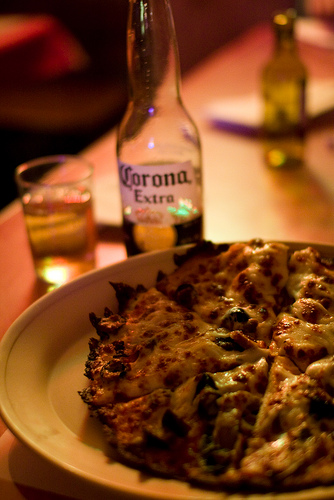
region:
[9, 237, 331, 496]
a white plate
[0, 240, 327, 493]
the plate has food on it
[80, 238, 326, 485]
pizza is on the plate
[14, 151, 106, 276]
a glass cup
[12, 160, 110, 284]
a drink is in the glass cup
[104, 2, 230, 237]
a glass bottle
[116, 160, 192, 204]
words on the glass bottle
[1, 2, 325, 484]
a counter with drinks and a plate on it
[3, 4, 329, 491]
The counter is a light brown color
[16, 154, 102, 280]
the drink is a tan color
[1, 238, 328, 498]
Pizza sitting on plate on table.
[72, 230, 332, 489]
Slices of pizza on plate.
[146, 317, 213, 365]
Melted cheese on pizza.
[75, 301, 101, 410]
Brown crust edge on pizza.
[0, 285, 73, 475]
Edge of plate pizza sitting on.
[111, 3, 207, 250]
Bottle of Corona beer sitting on table.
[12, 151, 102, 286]
Glass of Corona beer sitting on table.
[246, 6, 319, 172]
Empty beer bottle sitting on table.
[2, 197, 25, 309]
Edge of table plate sitting on.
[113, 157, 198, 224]
Lable on beer bottle.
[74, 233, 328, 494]
small pizza cut into wedges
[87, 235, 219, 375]
burnt edges of crust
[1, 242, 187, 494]
round edge of plate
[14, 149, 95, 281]
glass filled with beer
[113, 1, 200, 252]
curved outline of beer bottle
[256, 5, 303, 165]
green bottle in background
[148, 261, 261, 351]
black bubbles on surface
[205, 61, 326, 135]
purple and white object on table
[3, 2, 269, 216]
edge of long table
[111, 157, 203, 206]
dark writing on label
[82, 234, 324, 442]
this is a dish of food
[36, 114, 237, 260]
this is a brand of beer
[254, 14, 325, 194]
the glass bottle is green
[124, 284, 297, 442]
there is cheese on this food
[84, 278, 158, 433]
the crust is well done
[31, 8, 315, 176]
the background is blurry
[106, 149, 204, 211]
this is a brand of beer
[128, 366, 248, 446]
some kind of vegetables in the food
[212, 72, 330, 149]
a blurry purple device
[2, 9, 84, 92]
a blurry pink object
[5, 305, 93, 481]
The plate is the color white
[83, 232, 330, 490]
A personal pizza on the plate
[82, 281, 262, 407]
The slice of pizza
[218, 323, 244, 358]
The item on the pizza is black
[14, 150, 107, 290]
A glass of beer on the table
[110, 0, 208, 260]
The bottle of beer on the table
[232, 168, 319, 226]
The table is the color beige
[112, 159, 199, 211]
The logo on the bottle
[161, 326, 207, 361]
The cheese is the color white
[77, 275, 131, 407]
The crust on the pizza